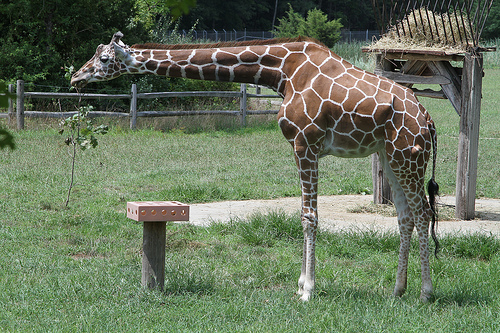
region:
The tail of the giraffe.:
[418, 111, 447, 263]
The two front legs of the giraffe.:
[287, 152, 334, 300]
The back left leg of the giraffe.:
[385, 179, 415, 301]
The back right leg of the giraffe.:
[397, 181, 436, 300]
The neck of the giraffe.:
[126, 44, 316, 79]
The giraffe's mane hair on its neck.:
[129, 39, 334, 59]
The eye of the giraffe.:
[102, 52, 110, 68]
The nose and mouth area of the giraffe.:
[56, 66, 96, 91]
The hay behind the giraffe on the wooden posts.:
[374, 15, 471, 62]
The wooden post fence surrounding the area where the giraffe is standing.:
[5, 75, 317, 132]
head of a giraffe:
[65, 29, 138, 92]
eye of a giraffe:
[95, 52, 115, 67]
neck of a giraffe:
[139, 34, 265, 85]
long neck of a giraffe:
[137, 25, 280, 94]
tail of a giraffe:
[423, 110, 448, 265]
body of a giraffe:
[278, 33, 432, 164]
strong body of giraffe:
[276, 38, 434, 156]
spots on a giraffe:
[300, 86, 415, 149]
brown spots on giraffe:
[296, 72, 413, 145]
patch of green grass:
[7, 237, 117, 321]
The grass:
[238, 291, 300, 328]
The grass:
[241, 265, 284, 324]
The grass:
[194, 249, 275, 321]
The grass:
[219, 286, 242, 313]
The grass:
[216, 277, 270, 326]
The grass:
[241, 294, 266, 320]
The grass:
[230, 234, 273, 285]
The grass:
[193, 285, 232, 322]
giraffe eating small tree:
[57, 40, 147, 120]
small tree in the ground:
[45, 62, 102, 229]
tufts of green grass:
[210, 211, 306, 248]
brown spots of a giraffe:
[280, 48, 381, 131]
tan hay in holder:
[359, 22, 481, 67]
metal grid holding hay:
[369, 7, 480, 42]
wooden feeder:
[366, 15, 486, 209]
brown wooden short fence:
[0, 74, 242, 124]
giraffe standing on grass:
[70, 30, 491, 329]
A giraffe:
[227, 31, 410, 291]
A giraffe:
[231, 63, 298, 216]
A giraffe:
[243, 101, 350, 293]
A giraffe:
[269, 54, 389, 251]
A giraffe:
[325, 100, 382, 245]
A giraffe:
[281, 94, 468, 331]